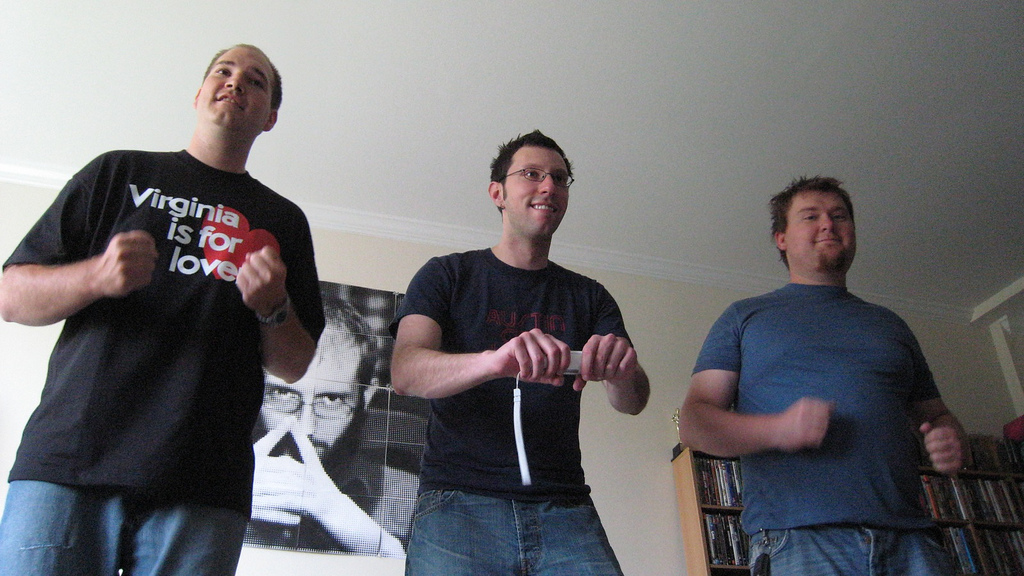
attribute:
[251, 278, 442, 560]
poster — black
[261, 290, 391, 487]
face — White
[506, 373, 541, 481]
strap — White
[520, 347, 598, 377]
wii remote — White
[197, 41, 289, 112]
hair — receding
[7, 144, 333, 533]
shirt — black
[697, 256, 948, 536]
t-shirt — blue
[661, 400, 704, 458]
award — gold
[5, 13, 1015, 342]
ceiling — white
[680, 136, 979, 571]
man — standing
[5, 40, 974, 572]
men — standing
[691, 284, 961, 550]
shirt — blue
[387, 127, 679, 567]
man — standing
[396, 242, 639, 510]
shirt — black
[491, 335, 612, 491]
remote — white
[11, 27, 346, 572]
man — standing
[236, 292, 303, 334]
watch — silver